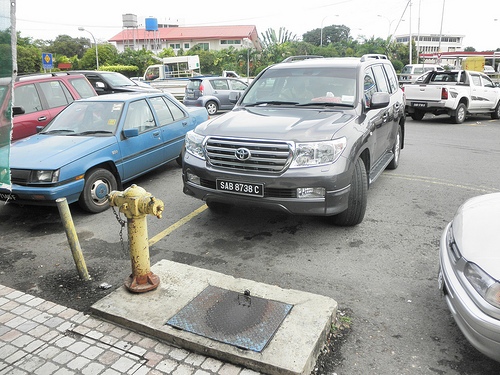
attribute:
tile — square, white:
[79, 345, 106, 361]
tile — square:
[1, 329, 20, 341]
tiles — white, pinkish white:
[1, 284, 262, 374]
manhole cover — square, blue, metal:
[164, 284, 293, 351]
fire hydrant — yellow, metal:
[107, 183, 166, 293]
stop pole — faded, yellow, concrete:
[54, 197, 93, 280]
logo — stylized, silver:
[235, 147, 252, 162]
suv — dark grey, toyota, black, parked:
[183, 54, 406, 227]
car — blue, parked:
[2, 90, 213, 213]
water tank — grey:
[121, 13, 140, 28]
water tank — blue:
[143, 15, 161, 32]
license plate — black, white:
[214, 177, 265, 197]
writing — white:
[219, 181, 263, 193]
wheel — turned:
[332, 156, 369, 227]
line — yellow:
[148, 201, 209, 248]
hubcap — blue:
[90, 179, 114, 205]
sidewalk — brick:
[0, 282, 266, 374]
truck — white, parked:
[403, 69, 500, 122]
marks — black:
[448, 90, 492, 103]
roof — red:
[107, 24, 261, 42]